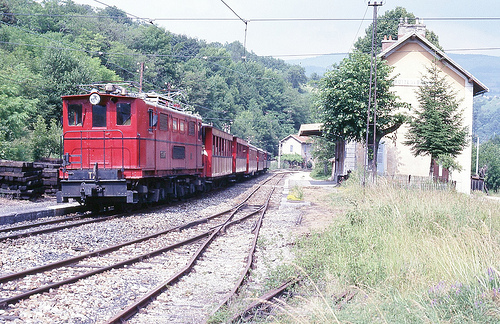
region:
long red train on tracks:
[0, 82, 291, 232]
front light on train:
[77, 85, 121, 108]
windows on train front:
[60, 98, 132, 136]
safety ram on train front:
[51, 168, 133, 217]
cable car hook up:
[61, 186, 106, 209]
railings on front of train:
[62, 116, 117, 179]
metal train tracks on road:
[190, 187, 309, 280]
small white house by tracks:
[316, 17, 471, 199]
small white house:
[268, 113, 327, 170]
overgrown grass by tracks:
[320, 191, 450, 316]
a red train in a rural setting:
[57, 86, 275, 205]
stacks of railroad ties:
[5, 160, 60, 196]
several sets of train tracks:
[7, 225, 236, 321]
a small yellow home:
[377, 43, 481, 200]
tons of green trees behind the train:
[6, 45, 317, 122]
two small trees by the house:
[324, 53, 465, 186]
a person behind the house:
[479, 165, 494, 193]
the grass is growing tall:
[330, 188, 497, 320]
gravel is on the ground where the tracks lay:
[4, 228, 174, 284]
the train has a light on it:
[80, 89, 105, 104]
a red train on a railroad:
[0, 56, 302, 317]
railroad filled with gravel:
[5, 208, 267, 317]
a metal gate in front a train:
[56, 125, 140, 200]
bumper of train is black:
[54, 165, 139, 208]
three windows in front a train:
[54, 89, 136, 136]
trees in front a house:
[299, 6, 490, 204]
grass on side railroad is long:
[277, 158, 497, 319]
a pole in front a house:
[356, 0, 399, 171]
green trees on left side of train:
[0, 0, 302, 199]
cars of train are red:
[51, 82, 278, 197]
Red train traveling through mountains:
[34, 80, 278, 193]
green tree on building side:
[330, 45, 410, 184]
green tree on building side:
[408, 73, 480, 185]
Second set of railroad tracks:
[96, 202, 403, 323]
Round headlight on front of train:
[82, 91, 116, 110]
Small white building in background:
[269, 123, 306, 180]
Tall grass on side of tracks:
[291, 208, 485, 300]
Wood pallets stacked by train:
[5, 153, 60, 194]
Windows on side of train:
[212, 138, 270, 153]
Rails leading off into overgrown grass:
[268, 263, 350, 319]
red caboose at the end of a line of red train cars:
[55, 82, 210, 204]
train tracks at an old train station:
[7, 201, 353, 321]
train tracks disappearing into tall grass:
[227, 262, 410, 319]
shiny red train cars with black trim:
[58, 83, 273, 202]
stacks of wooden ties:
[2, 156, 48, 200]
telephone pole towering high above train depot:
[345, 0, 400, 174]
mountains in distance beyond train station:
[231, 39, 497, 112]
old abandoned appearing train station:
[273, 20, 490, 195]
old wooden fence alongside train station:
[350, 168, 464, 196]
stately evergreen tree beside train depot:
[402, 51, 469, 183]